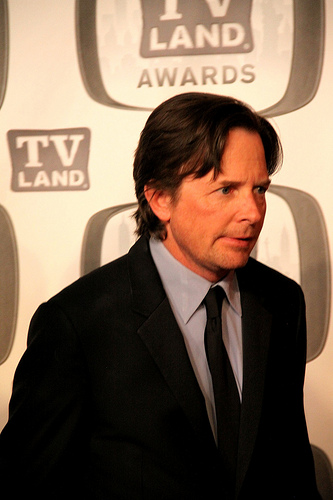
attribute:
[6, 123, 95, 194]
tv land award logo — gray, white, in background, black, large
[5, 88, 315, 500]
man — michael j fox, looking to side, at tv land awards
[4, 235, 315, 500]
suit — black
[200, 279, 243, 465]
tie — black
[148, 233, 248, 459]
shirt — light blue, blue, grey, grey collared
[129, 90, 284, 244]
hair — medium length, dark brown, brown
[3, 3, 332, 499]
wall — tan, gray, white, for tv land awards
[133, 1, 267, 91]
logo — gray, black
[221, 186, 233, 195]
eye — blue, open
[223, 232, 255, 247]
mouth — closed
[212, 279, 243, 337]
shadow — black